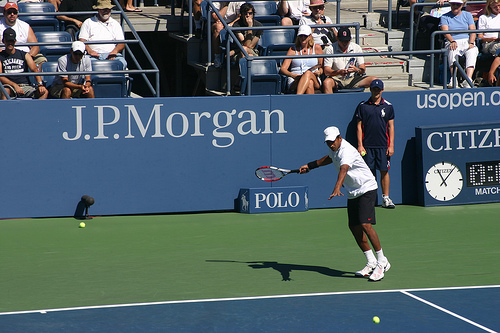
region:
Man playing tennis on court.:
[243, 121, 392, 293]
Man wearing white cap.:
[319, 123, 341, 145]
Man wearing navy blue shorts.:
[343, 183, 382, 230]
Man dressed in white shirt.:
[327, 138, 381, 201]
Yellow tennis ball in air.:
[367, 313, 385, 328]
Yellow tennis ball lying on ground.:
[68, 217, 91, 232]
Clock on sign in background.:
[425, 156, 467, 208]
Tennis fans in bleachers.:
[208, 8, 413, 89]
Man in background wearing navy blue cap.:
[367, 77, 387, 95]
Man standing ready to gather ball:
[355, 80, 395, 209]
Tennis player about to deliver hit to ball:
[255, 121, 392, 283]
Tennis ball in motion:
[371, 315, 379, 326]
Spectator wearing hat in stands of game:
[50, 44, 101, 101]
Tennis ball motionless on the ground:
[78, 221, 86, 228]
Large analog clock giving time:
[423, 159, 464, 202]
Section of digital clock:
[468, 161, 499, 186]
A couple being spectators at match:
[284, 24, 383, 91]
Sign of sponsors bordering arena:
[239, 185, 311, 212]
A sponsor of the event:
[60, 99, 288, 146]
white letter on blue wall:
[288, 190, 298, 206]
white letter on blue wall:
[57, 100, 82, 140]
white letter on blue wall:
[91, 101, 118, 141]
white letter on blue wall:
[122, 101, 162, 138]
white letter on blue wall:
[165, 110, 186, 135]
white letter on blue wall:
[190, 110, 211, 138]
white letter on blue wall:
[210, 107, 235, 145]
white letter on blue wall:
[236, 108, 258, 134]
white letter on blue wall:
[260, 105, 286, 135]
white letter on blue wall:
[255, 188, 265, 208]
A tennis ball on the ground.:
[78, 220, 88, 227]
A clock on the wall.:
[423, 160, 465, 205]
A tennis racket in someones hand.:
[256, 165, 301, 183]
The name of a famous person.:
[61, 104, 287, 147]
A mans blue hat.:
[368, 79, 384, 91]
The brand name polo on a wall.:
[239, 187, 310, 213]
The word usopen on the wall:
[414, 93, 486, 108]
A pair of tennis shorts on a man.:
[345, 186, 379, 228]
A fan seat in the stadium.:
[240, 57, 283, 95]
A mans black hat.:
[0, 28, 16, 43]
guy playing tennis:
[252, 126, 408, 282]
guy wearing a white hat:
[245, 110, 407, 302]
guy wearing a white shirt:
[240, 116, 405, 297]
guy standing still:
[345, 75, 405, 220]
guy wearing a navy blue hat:
[343, 72, 400, 227]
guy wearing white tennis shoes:
[245, 110, 396, 301]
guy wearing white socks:
[242, 103, 413, 311]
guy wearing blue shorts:
[348, 75, 405, 216]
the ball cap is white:
[325, 128, 338, 140]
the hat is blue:
[368, 77, 385, 90]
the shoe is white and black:
[368, 261, 389, 279]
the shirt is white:
[328, 145, 374, 192]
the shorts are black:
[341, 193, 378, 227]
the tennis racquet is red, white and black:
[250, 158, 294, 185]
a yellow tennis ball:
[372, 311, 379, 323]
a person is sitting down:
[2, 30, 44, 95]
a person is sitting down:
[58, 32, 97, 95]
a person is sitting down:
[3, 4, 44, 65]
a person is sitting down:
[73, 2, 134, 66]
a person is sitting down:
[228, 6, 261, 64]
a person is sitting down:
[277, 21, 324, 97]